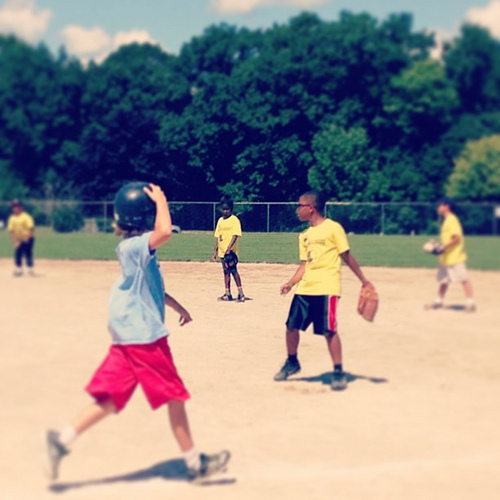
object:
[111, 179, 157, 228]
helmet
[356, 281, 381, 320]
baseball mitt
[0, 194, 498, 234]
fence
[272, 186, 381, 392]
boy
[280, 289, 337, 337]
shorts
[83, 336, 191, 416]
shorts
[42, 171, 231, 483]
boy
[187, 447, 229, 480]
socks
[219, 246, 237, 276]
shorts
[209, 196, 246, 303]
boy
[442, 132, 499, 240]
trees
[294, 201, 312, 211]
eyeglasses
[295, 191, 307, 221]
face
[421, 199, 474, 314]
boy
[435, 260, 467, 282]
shorts